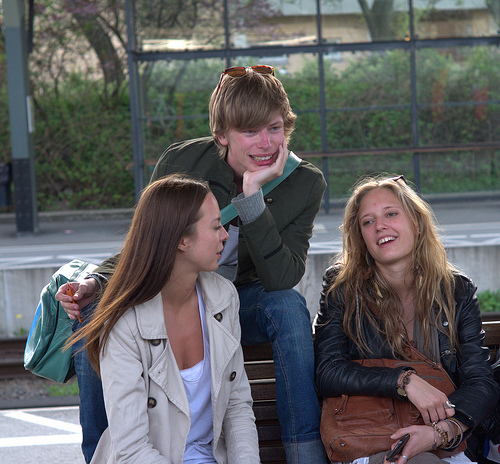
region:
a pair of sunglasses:
[213, 65, 275, 93]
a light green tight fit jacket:
[81, 138, 317, 282]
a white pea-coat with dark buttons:
[92, 273, 262, 462]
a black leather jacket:
[319, 266, 499, 426]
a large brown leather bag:
[323, 347, 448, 458]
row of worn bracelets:
[426, 411, 469, 451]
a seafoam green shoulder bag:
[20, 147, 300, 387]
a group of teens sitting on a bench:
[25, 65, 493, 462]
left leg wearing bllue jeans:
[236, 281, 326, 461]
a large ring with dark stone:
[442, 396, 456, 406]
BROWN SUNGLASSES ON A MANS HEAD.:
[211, 58, 283, 83]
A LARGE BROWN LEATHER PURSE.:
[323, 354, 462, 457]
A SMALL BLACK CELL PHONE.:
[384, 435, 415, 457]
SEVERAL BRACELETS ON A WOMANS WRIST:
[430, 418, 465, 449]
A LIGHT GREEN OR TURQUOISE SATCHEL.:
[11, 243, 91, 379]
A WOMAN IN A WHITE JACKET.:
[64, 170, 262, 454]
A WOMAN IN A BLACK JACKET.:
[303, 170, 498, 457]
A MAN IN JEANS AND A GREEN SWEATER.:
[73, 42, 331, 451]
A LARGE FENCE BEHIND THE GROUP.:
[108, 1, 495, 203]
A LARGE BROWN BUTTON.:
[226, 366, 242, 382]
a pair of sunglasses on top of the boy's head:
[213, 60, 278, 100]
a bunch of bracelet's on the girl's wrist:
[428, 413, 464, 453]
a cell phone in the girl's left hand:
[386, 427, 410, 462]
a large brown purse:
[319, 343, 466, 462]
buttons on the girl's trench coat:
[142, 333, 162, 413]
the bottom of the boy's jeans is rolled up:
[279, 428, 324, 462]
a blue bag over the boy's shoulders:
[18, 148, 305, 385]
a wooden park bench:
[109, 313, 498, 463]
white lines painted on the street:
[0, 406, 87, 451]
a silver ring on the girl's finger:
[443, 398, 455, 411]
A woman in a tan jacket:
[90, 172, 261, 462]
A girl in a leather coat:
[315, 174, 497, 462]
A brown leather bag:
[316, 289, 458, 461]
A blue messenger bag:
[23, 151, 310, 385]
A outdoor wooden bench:
[225, 312, 499, 462]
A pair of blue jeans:
[72, 284, 327, 462]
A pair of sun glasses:
[211, 63, 274, 96]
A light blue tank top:
[180, 279, 215, 462]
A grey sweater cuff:
[229, 192, 265, 224]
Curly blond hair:
[314, 175, 466, 374]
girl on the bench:
[330, 183, 462, 449]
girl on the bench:
[105, 195, 255, 457]